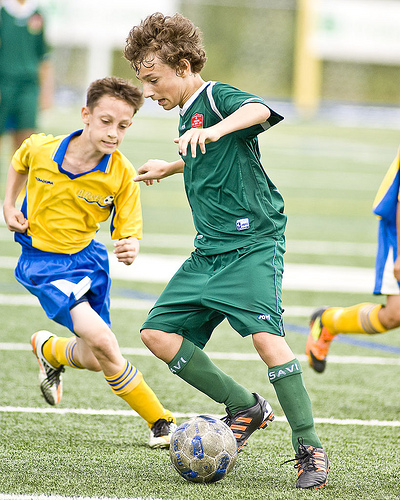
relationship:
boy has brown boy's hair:
[127, 32, 355, 491] [123, 12, 207, 77]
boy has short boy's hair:
[3, 76, 179, 450] [85, 76, 144, 115]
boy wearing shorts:
[3, 76, 179, 450] [7, 244, 122, 318]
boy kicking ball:
[123, 8, 330, 490] [170, 415, 237, 482]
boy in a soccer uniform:
[123, 8, 330, 490] [138, 81, 288, 350]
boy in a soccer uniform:
[123, 8, 330, 490] [10, 128, 144, 256]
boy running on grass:
[123, 8, 330, 490] [1, 122, 398, 498]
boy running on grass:
[1, 76, 179, 449] [1, 122, 398, 498]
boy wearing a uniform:
[1, 76, 179, 449] [13, 130, 141, 331]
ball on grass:
[170, 415, 237, 482] [59, 396, 110, 472]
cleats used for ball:
[225, 396, 274, 454] [170, 415, 237, 482]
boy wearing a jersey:
[3, 76, 179, 450] [9, 128, 145, 254]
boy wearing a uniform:
[123, 8, 330, 490] [133, 88, 342, 438]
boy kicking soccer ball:
[123, 8, 330, 490] [149, 398, 265, 473]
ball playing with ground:
[170, 415, 237, 482] [0, 120, 398, 498]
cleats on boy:
[31, 329, 64, 405] [1, 76, 179, 449]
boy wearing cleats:
[123, 8, 330, 490] [223, 393, 273, 455]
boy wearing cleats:
[1, 76, 179, 449] [31, 329, 64, 405]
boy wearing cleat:
[123, 8, 330, 490] [218, 393, 274, 451]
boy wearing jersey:
[3, 76, 179, 450] [11, 133, 143, 254]